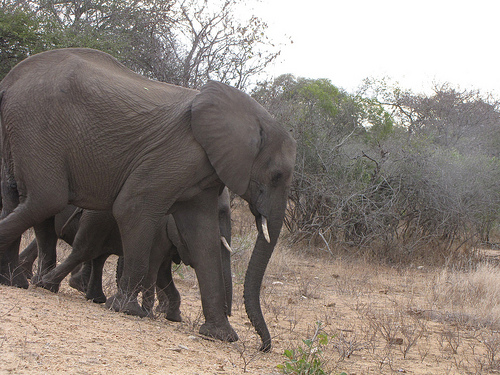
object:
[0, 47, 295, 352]
elephant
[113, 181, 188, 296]
leg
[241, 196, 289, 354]
trunk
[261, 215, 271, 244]
tusk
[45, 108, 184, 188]
skin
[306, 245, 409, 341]
grass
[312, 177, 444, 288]
no leaves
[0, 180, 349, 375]
hill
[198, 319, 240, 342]
feet